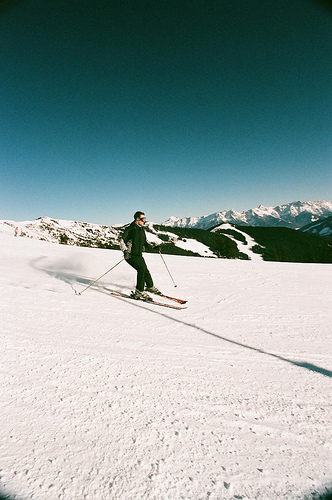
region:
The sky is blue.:
[71, 44, 297, 197]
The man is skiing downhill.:
[103, 200, 201, 325]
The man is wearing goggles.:
[128, 211, 152, 223]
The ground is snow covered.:
[44, 315, 175, 453]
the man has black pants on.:
[115, 235, 171, 301]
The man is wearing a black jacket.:
[111, 217, 157, 266]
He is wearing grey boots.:
[74, 218, 192, 306]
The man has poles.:
[67, 211, 193, 312]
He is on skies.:
[78, 214, 185, 329]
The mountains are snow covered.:
[67, 183, 327, 256]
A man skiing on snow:
[64, 183, 200, 331]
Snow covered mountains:
[27, 182, 331, 256]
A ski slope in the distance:
[208, 211, 277, 267]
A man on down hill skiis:
[112, 200, 198, 324]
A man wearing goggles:
[129, 207, 154, 230]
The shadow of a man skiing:
[16, 228, 130, 301]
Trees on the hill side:
[227, 208, 331, 274]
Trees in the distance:
[149, 203, 262, 265]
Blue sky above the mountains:
[14, 148, 315, 230]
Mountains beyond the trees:
[157, 188, 331, 237]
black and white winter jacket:
[122, 224, 148, 260]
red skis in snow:
[116, 286, 186, 309]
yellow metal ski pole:
[155, 246, 179, 289]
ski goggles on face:
[134, 216, 145, 222]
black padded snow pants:
[124, 253, 155, 290]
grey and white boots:
[133, 285, 158, 298]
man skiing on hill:
[120, 211, 182, 307]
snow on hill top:
[214, 223, 266, 260]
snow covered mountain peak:
[203, 199, 325, 227]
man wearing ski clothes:
[115, 212, 161, 301]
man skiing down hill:
[74, 207, 192, 318]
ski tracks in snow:
[42, 320, 307, 379]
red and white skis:
[104, 284, 188, 312]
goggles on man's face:
[134, 216, 148, 222]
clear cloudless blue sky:
[53, 87, 320, 188]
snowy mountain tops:
[183, 200, 319, 229]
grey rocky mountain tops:
[239, 222, 325, 259]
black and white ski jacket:
[117, 222, 152, 256]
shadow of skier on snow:
[34, 259, 119, 299]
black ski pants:
[125, 251, 155, 292]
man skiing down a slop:
[74, 202, 203, 314]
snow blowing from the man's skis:
[31, 249, 115, 293]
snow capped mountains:
[0, 193, 327, 234]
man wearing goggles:
[131, 209, 157, 225]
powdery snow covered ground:
[4, 148, 329, 496]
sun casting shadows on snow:
[23, 244, 327, 382]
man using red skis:
[103, 276, 195, 312]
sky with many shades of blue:
[0, 3, 324, 200]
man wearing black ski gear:
[110, 202, 164, 304]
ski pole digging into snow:
[73, 240, 123, 304]